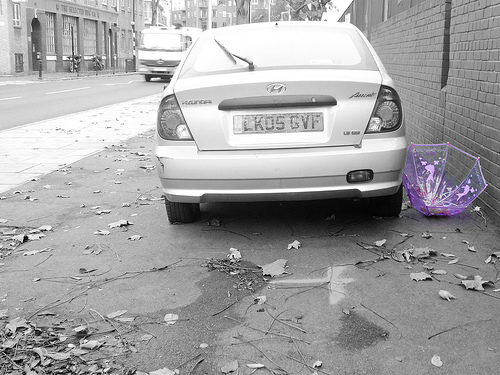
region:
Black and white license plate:
[228, 101, 329, 146]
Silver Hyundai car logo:
[179, 93, 221, 121]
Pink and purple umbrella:
[376, 104, 492, 232]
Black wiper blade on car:
[207, 31, 263, 78]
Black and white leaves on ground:
[7, 90, 499, 373]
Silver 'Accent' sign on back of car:
[349, 83, 379, 102]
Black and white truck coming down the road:
[124, 18, 201, 91]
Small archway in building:
[27, 14, 62, 71]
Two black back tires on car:
[146, 184, 421, 254]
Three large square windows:
[35, 7, 101, 67]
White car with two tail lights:
[151, 17, 413, 227]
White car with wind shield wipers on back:
[151, 17, 413, 224]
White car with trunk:
[152, 17, 411, 225]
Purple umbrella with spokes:
[398, 139, 488, 217]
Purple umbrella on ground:
[0, 126, 499, 373]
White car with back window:
[151, 17, 411, 232]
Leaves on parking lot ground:
[0, 91, 499, 370]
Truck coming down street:
[0, 23, 211, 184]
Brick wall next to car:
[151, 14, 498, 225]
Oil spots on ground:
[0, 126, 499, 373]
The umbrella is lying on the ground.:
[388, 124, 490, 244]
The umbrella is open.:
[380, 118, 495, 240]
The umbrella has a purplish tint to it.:
[397, 128, 493, 241]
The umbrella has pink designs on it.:
[388, 121, 497, 235]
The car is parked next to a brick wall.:
[133, 10, 498, 262]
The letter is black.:
[236, 113, 256, 134]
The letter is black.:
[249, 112, 266, 134]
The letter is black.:
[259, 113, 278, 135]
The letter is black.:
[288, 110, 300, 134]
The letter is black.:
[309, 109, 324, 132]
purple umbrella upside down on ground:
[402, 141, 487, 218]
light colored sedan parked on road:
[154, 19, 406, 224]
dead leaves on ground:
[402, 226, 498, 300]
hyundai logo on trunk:
[180, 98, 213, 107]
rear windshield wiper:
[212, 33, 254, 69]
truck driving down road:
[133, 21, 200, 81]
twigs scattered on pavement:
[214, 283, 331, 373]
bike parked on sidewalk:
[65, 50, 85, 71]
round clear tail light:
[375, 98, 399, 130]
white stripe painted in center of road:
[43, 83, 93, 98]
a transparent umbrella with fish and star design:
[401, 141, 493, 220]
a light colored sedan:
[151, 16, 417, 228]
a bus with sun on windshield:
[131, 25, 196, 80]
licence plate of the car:
[234, 111, 332, 136]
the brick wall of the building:
[363, 0, 498, 239]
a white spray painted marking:
[262, 258, 369, 308]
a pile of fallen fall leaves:
[1, 308, 181, 373]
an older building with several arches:
[0, 3, 166, 83]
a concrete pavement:
[1, 76, 498, 373]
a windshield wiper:
[203, 36, 263, 74]